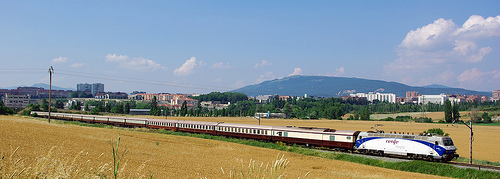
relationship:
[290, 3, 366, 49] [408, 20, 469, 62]
sky has clouds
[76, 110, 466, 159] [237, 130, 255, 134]
train has windows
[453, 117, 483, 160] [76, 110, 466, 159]
lamp post in front of train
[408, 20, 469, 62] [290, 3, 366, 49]
clouds in sky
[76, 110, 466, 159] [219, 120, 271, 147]
train has compartment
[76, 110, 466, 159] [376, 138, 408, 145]
train has logo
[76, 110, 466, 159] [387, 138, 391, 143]
train has letters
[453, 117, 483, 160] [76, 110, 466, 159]
lamp post near train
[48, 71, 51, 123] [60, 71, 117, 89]
pole has electrice lines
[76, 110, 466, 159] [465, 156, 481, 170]
train has tracks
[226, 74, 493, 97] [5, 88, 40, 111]
mountain behind buildings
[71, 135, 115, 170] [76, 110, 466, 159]
field next to train